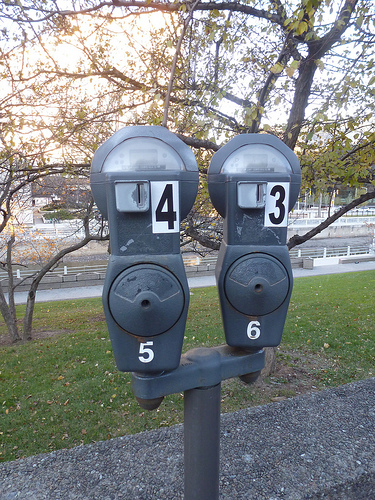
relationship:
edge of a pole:
[180, 366, 226, 394] [182, 380, 219, 499]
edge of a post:
[182, 357, 223, 387] [178, 398, 242, 476]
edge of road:
[315, 477, 356, 497] [47, 245, 349, 285]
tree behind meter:
[95, 1, 374, 253] [206, 134, 300, 348]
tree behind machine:
[0, 155, 108, 343] [89, 125, 198, 372]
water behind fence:
[19, 214, 365, 256] [8, 240, 374, 272]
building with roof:
[28, 173, 93, 215] [29, 174, 90, 197]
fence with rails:
[12, 241, 373, 282] [14, 230, 197, 326]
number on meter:
[246, 318, 263, 342] [206, 134, 300, 348]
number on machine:
[135, 339, 156, 364] [89, 125, 198, 372]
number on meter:
[135, 339, 156, 364] [206, 134, 300, 348]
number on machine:
[246, 318, 263, 339] [89, 125, 198, 372]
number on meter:
[270, 181, 283, 221] [206, 134, 300, 348]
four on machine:
[156, 183, 176, 229] [89, 125, 198, 372]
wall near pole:
[2, 376, 373, 498] [182, 380, 219, 499]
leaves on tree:
[0, 218, 62, 268] [0, 155, 108, 343]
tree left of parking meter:
[0, 155, 108, 343] [89, 123, 302, 496]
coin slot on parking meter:
[135, 181, 143, 204] [89, 123, 302, 496]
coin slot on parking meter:
[255, 182, 260, 205] [89, 123, 302, 496]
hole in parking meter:
[137, 296, 153, 312] [82, 116, 200, 423]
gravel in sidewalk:
[1, 372, 373, 497] [1, 352, 373, 498]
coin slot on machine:
[255, 182, 260, 202] [89, 125, 198, 372]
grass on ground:
[1, 270, 373, 447] [3, 258, 373, 498]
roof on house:
[31, 175, 86, 195] [33, 196, 55, 207]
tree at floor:
[0, 155, 108, 343] [0, 388, 375, 500]